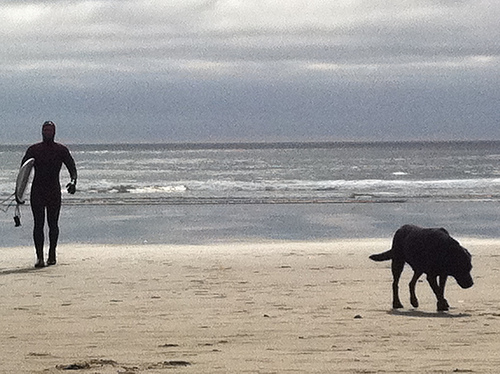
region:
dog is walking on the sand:
[372, 219, 477, 327]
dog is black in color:
[374, 220, 478, 317]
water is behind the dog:
[342, 148, 447, 243]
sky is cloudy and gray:
[180, 40, 368, 107]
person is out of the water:
[17, 121, 86, 269]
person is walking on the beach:
[15, 120, 85, 267]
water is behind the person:
[56, 139, 162, 215]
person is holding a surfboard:
[9, 122, 89, 264]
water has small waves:
[132, 158, 312, 201]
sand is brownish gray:
[132, 255, 339, 345]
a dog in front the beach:
[356, 148, 488, 331]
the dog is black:
[362, 210, 480, 320]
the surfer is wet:
[10, 110, 89, 264]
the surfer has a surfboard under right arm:
[7, 112, 82, 270]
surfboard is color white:
[11, 157, 36, 207]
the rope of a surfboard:
[1, 191, 28, 231]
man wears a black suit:
[10, 114, 82, 271]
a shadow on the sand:
[386, 298, 498, 325]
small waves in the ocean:
[11, 135, 488, 204]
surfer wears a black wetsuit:
[3, 112, 83, 270]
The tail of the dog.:
[365, 248, 392, 263]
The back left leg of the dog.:
[392, 261, 402, 308]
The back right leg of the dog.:
[409, 270, 420, 307]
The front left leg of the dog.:
[424, 273, 447, 313]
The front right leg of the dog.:
[440, 277, 448, 309]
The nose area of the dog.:
[467, 280, 474, 290]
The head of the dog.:
[448, 247, 475, 292]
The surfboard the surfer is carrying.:
[12, 159, 32, 204]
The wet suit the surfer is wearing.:
[20, 120, 75, 270]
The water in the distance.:
[5, 141, 498, 198]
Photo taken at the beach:
[3, 17, 493, 361]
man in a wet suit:
[1, 93, 98, 291]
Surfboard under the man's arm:
[8, 137, 40, 223]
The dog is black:
[353, 208, 488, 321]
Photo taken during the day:
[1, 13, 493, 365]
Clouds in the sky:
[12, 10, 484, 93]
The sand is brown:
[20, 211, 492, 365]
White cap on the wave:
[17, 168, 486, 208]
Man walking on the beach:
[20, 98, 104, 290]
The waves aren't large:
[6, 143, 493, 207]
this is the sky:
[274, 25, 347, 70]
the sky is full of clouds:
[264, 9, 434, 140]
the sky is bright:
[163, 14, 308, 114]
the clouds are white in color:
[119, 18, 259, 113]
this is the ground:
[168, 287, 237, 331]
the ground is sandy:
[148, 273, 252, 359]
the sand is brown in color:
[214, 300, 279, 339]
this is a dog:
[368, 228, 468, 301]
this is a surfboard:
[11, 158, 31, 199]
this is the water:
[273, 140, 349, 167]